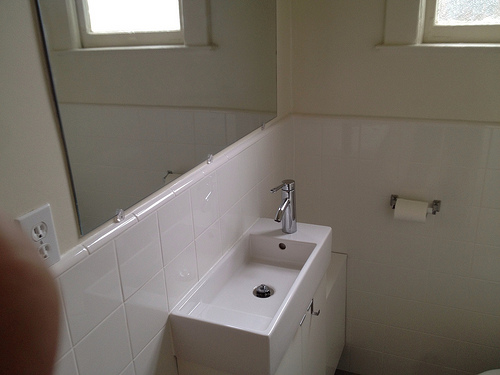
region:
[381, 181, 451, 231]
Partial roll of toilet paper on wall mounted dispenser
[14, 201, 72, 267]
Wall mounted electrical receptacle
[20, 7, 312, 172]
Mirror mounted on tan wall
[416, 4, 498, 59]
Frosted glass window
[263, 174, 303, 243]
Chrome water faucet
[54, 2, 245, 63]
Reflection of window in mirror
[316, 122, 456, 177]
White ceramic wall tiles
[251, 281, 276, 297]
Chrome sink drain with stopper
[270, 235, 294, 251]
Overflow hole in white sink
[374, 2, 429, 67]
Frame around frosted window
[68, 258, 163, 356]
white tiles on wall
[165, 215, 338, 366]
white porcelain bathroom sink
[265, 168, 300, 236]
chrome faucet on sink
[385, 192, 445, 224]
chrome toilet paper holder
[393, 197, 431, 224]
roll of white toilet paper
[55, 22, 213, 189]
mirror hanging on wall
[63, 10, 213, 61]
reflection of window in mirror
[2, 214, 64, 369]
tip of finger in photo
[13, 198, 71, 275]
double electrical outlet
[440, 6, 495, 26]
frosted glass window pane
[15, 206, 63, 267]
2 outlets in wall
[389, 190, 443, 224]
Toilet paper on toilet paper holder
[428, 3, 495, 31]
window with crackled glass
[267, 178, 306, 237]
Silver sink faucet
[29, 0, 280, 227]
Bathroom mirror on wall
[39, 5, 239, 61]
window reflecting in mirror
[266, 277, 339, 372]
White cabinet under sink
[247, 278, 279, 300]
drain in bottom of sink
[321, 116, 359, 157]
White shiny tile on wall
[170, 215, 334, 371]
Rectangle white sink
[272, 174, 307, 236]
silver faucet of white sink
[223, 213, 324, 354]
white sink in bathroom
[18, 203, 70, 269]
white electrical outlet in bathroom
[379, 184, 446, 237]
white roll of toilet paper in bathroom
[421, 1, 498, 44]
white window in bathroom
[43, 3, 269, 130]
mirror in bathroom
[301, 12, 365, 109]
white wall in bathroom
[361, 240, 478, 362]
white wall in bathroom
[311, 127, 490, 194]
white tiles in bathroom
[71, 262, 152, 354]
white wall tiles in bathroom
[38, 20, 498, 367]
a bathroom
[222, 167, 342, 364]
a sink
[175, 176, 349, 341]
a rectangle shaped sink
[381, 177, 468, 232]
a roll of toilet paper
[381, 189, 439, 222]
toilet paper on a dispenser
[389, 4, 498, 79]
the bathroom has a window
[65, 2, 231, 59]
a window reflected in the mirror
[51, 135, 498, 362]
the bottom half of the wall is white tile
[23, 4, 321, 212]
a mirror is on the wall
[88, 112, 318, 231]
plastic pegs hold the mirror up